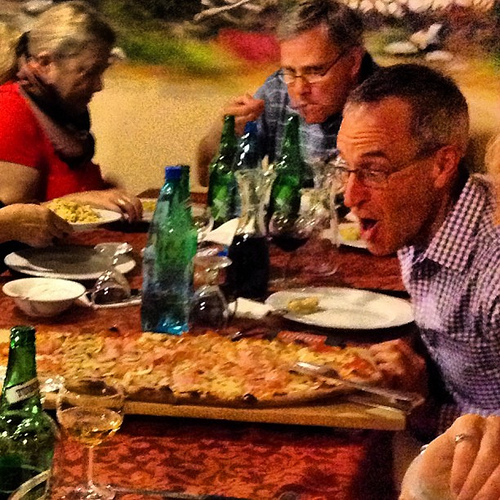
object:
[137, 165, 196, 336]
bottle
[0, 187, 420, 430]
table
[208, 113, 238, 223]
bottle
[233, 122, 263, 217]
bottle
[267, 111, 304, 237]
bottle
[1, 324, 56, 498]
bottle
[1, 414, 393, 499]
table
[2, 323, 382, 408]
pizza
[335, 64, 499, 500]
man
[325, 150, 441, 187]
glasses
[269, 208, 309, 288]
glass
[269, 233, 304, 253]
wine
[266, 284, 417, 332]
plate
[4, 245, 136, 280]
plate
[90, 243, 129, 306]
glass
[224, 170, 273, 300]
carafe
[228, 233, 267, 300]
wine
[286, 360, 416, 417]
tong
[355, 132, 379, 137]
wrinkles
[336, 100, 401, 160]
forehead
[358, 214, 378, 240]
mouth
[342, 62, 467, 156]
hair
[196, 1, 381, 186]
man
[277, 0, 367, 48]
hair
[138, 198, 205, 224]
plate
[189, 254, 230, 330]
glass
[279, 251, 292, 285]
stem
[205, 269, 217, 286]
stem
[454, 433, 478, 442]
ring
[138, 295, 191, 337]
water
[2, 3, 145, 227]
lady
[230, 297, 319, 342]
spoon